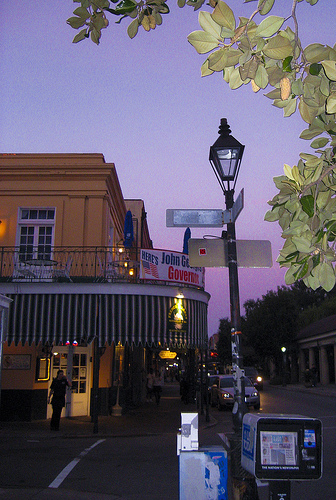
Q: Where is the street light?
A: On black metal pole.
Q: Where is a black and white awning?
A: Yellow building on left.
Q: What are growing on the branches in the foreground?
A: Leaves.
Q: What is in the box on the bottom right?
A: Newspapers.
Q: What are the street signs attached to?
A: Street lamp.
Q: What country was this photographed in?
A: America.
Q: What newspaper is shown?
A: USA today.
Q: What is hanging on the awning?
A: Campaign poster.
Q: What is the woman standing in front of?
A: The doorway.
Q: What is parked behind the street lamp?
A: White car.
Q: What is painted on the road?
A: White line.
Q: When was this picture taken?
A: Evening.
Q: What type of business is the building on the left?
A: Restaurant.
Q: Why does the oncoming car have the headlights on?
A: It is dark outside.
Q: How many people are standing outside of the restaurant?
A: One.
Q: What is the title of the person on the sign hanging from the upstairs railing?
A: Governor.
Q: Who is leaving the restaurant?
A: An employee.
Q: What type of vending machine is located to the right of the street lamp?
A: Newspaper.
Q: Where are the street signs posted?
A: On the streep lamp.